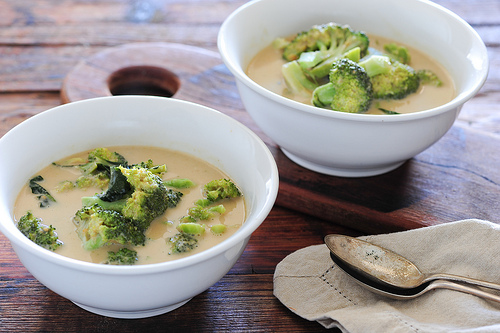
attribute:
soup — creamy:
[10, 143, 252, 264]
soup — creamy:
[239, 18, 460, 116]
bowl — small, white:
[8, 87, 275, 319]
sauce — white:
[66, 163, 208, 245]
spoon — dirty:
[310, 214, 499, 323]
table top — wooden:
[59, 66, 477, 327]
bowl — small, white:
[213, 0, 490, 178]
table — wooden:
[0, 2, 498, 332]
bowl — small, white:
[80, 25, 379, 160]